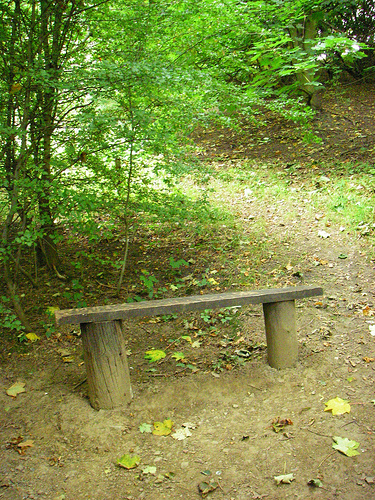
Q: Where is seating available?
A: The bench.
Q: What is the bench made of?
A: Wood.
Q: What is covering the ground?
A: Dirt.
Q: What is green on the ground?
A: Dirt.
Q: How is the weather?
A: Sunny.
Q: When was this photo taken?
A: In the daytime.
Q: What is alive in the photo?
A: Trees.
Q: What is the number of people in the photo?
A: Zero.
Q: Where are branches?
A: On trees.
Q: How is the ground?
A: Dry.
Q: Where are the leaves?
A: On branches.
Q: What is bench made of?
A: Wood.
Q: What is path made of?
A: Dirt and grass.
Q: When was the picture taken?
A: During the day.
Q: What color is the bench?
A: Brown.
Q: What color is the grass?
A: Green.